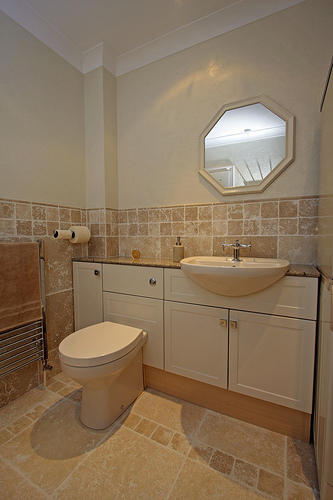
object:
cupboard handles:
[220, 318, 239, 328]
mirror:
[201, 100, 289, 185]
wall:
[117, 0, 329, 263]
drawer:
[101, 261, 165, 300]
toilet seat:
[60, 318, 142, 364]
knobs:
[93, 268, 101, 276]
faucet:
[221, 238, 252, 256]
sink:
[179, 254, 290, 295]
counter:
[71, 254, 320, 278]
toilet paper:
[53, 228, 72, 242]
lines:
[112, 416, 322, 498]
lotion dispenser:
[172, 234, 185, 264]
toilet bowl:
[57, 317, 148, 432]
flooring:
[0, 365, 317, 500]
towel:
[0, 240, 42, 332]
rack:
[0, 243, 44, 398]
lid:
[56, 319, 143, 367]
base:
[143, 365, 321, 444]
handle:
[218, 317, 226, 327]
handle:
[229, 320, 238, 329]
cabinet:
[163, 299, 319, 416]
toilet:
[58, 318, 149, 432]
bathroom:
[2, 0, 332, 497]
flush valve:
[147, 277, 158, 287]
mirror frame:
[197, 92, 294, 194]